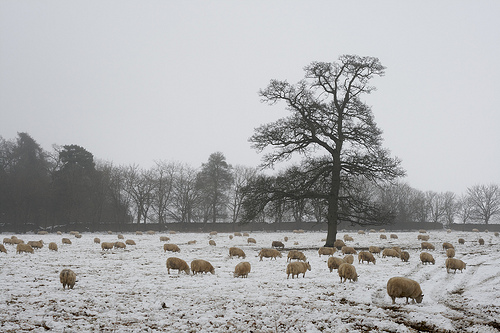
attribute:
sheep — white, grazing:
[234, 261, 251, 280]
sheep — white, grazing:
[166, 257, 190, 276]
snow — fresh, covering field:
[0, 231, 500, 332]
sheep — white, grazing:
[287, 261, 312, 277]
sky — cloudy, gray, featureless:
[0, 0, 500, 224]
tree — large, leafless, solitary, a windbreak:
[248, 54, 407, 247]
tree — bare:
[145, 160, 184, 223]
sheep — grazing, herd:
[446, 258, 466, 274]